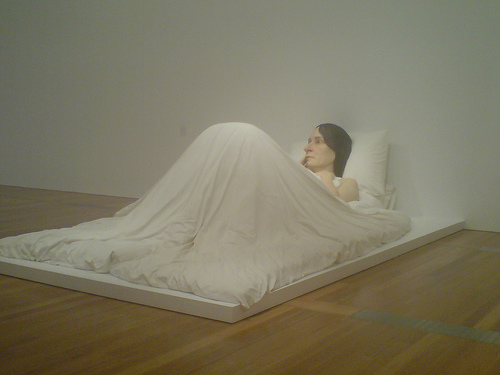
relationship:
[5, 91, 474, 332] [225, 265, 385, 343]
bed on floor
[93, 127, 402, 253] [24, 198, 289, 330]
bed on floor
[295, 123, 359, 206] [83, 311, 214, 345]
woman lying on floor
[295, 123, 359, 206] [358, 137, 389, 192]
woman resting on pillow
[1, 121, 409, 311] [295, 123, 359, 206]
bed sheet on woman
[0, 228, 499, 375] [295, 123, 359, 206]
floor beneath woman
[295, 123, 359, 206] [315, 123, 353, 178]
woman with hair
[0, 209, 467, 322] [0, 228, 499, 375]
bed on floor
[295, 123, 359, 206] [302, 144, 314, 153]
woman with a nose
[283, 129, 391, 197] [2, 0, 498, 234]
pillow against wall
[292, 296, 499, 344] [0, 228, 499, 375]
line on floor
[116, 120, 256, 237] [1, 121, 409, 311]
wrinkle on bed sheet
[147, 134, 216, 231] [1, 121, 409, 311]
wrinkle on bed sheet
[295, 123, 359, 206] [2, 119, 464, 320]
woman laying in bed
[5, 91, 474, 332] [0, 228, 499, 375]
bed laying on floor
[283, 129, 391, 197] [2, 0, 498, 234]
pillow against a wall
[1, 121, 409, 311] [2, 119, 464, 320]
bed sheet on top of a bed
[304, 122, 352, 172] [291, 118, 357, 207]
head of a woman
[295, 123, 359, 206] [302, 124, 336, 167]
woman with a face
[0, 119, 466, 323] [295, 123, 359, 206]
sculpture of woman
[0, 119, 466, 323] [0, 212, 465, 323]
sculpture of bed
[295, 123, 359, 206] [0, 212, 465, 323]
woman in bed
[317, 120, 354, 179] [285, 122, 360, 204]
hair of woman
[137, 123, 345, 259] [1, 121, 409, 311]
lump under bed sheet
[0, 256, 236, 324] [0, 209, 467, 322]
edge of bed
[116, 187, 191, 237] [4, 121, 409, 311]
wrinkle in bed sheet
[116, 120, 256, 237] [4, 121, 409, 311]
wrinkle in bed sheet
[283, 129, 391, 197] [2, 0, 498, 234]
pillow propped against wall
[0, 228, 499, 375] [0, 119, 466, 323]
floor under sculpture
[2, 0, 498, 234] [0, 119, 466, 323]
wall behind sculpture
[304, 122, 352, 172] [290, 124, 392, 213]
head on pillow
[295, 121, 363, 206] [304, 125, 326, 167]
woman has face